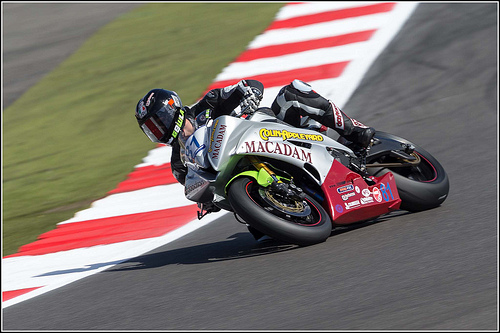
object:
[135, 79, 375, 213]
man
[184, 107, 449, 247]
motorcycle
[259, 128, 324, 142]
word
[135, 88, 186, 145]
helmet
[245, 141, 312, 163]
word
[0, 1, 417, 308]
stripes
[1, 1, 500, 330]
track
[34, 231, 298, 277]
shadow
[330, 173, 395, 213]
decals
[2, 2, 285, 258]
grass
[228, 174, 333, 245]
tire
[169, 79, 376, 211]
suit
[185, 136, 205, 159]
number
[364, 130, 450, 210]
tire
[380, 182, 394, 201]
number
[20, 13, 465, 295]
day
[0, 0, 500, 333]
scene